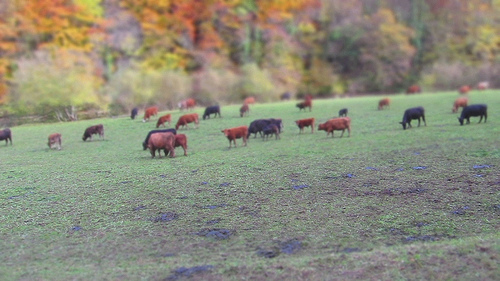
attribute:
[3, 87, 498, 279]
grass — green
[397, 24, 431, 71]
leaves — green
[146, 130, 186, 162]
cow — adult, brown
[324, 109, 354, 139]
calf — young, brown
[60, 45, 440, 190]
cows — black